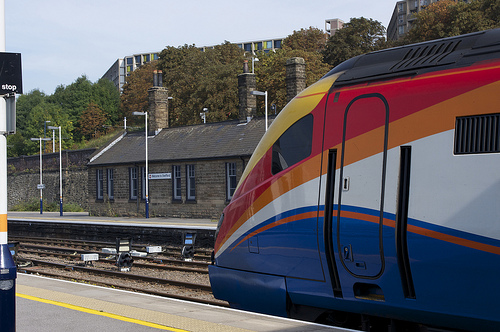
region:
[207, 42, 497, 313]
train pulling into station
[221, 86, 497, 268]
stripes on side of train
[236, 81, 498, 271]
orange stripes on side of train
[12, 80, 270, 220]
light poles on other side of platform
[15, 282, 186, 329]
yellow stripe on platform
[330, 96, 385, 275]
closed door of train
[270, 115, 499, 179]
windows of train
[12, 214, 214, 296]
track that train is on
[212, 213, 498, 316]
blue portion of train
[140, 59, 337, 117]
chimneys of brick building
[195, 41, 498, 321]
multicolored train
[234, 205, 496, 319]
orange stripe through blue paint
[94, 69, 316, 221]
brick building with chimneys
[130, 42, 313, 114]
tall trees with browning leaves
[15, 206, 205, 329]
train track between two platforms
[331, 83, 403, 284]
door on a train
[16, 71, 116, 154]
green bushy tree tops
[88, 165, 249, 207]
row of windows on a building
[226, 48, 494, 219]
red orange and yellow colors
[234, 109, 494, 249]
white stripe going through other colors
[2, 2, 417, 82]
a sky with clouds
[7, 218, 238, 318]
a few brown tracks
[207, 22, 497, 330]
a multi color train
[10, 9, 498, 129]
a row of trees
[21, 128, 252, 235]
a train station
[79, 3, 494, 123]
buildings in the background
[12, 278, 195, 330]
a yellow line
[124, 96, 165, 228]
a gray street light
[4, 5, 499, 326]
a scene outside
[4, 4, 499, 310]
a scene happening during the day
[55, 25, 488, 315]
colorful train car at station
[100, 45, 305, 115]
building on hill covered with windows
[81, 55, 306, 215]
stone house with chimneys on platform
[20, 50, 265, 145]
trees growing behind ticket station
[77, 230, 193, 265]
rectangular objects covering tracks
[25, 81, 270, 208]
lampposts along platform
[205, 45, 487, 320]
vivid stripes and blocks in primary colors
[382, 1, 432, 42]
angled building behind top of train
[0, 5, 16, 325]
safety pole on side of platform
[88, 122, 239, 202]
double windows under slanted roof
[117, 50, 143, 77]
Glass windows on building in the background.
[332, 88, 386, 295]
Door on side of train.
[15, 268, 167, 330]
Yellow painted line on the road.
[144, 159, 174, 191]
Sign on side of the building.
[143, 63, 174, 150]
Chimney stack on the roof.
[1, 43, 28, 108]
Train stop sign on pole.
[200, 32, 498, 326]
Modern train on the tracks.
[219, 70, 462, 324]
Blue, white, orange, red and yellow stripes on train.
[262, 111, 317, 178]
Window on side of the train.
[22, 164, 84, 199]
Brown stone wall in background.